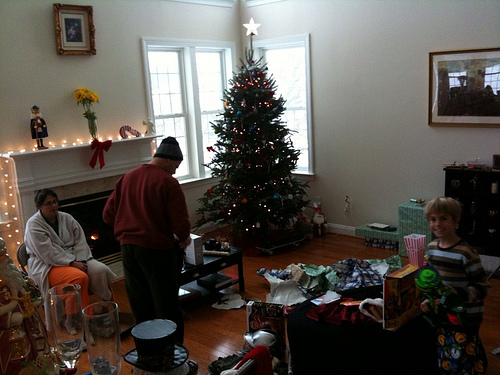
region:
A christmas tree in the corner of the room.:
[201, 13, 313, 248]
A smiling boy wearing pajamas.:
[407, 191, 490, 373]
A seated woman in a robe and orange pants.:
[19, 188, 114, 320]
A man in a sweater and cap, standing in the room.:
[91, 135, 203, 338]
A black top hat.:
[118, 318, 193, 369]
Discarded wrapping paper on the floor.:
[253, 260, 373, 310]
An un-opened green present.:
[396, 191, 430, 261]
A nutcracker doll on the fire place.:
[24, 105, 47, 148]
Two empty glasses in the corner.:
[41, 282, 124, 374]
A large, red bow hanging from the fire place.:
[86, 140, 116, 170]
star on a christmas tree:
[240, 11, 271, 42]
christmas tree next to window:
[205, 50, 305, 230]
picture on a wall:
[420, 43, 487, 135]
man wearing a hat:
[122, 126, 185, 297]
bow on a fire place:
[85, 136, 116, 171]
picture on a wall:
[41, 0, 113, 63]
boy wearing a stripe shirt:
[418, 195, 480, 270]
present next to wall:
[350, 213, 395, 253]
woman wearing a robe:
[28, 185, 108, 290]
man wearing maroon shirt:
[99, 130, 196, 269]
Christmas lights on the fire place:
[58, 130, 116, 147]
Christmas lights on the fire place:
[4, 136, 43, 169]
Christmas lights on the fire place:
[58, 114, 176, 154]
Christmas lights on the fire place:
[1, 141, 28, 257]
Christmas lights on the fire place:
[17, 125, 165, 143]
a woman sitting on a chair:
[23, 177, 113, 316]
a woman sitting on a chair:
[10, 178, 151, 357]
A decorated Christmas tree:
[195, 12, 325, 266]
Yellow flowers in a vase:
[62, 85, 107, 140]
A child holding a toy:
[404, 192, 490, 372]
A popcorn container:
[395, 227, 426, 269]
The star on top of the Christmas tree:
[235, 15, 262, 36]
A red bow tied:
[85, 136, 115, 171]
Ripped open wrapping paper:
[256, 250, 391, 306]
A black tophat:
[119, 315, 197, 370]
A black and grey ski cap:
[153, 133, 188, 162]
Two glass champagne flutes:
[34, 280, 126, 372]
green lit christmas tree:
[216, 39, 316, 262]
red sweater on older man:
[102, 185, 216, 282]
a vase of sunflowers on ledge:
[65, 90, 132, 152]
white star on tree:
[230, 14, 275, 60]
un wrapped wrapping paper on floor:
[245, 240, 422, 295]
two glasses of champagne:
[25, 243, 117, 370]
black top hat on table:
[127, 311, 197, 368]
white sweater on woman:
[21, 223, 133, 292]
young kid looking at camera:
[425, 194, 495, 343]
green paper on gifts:
[374, 173, 468, 294]